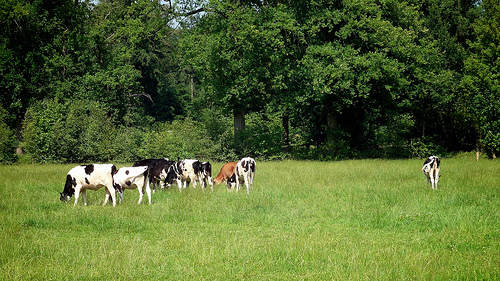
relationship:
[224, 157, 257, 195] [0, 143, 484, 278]
black and white cow in field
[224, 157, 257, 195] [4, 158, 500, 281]
black and white cow in field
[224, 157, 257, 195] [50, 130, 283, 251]
black and white cow in green grass field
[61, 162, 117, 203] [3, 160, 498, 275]
cow eating grass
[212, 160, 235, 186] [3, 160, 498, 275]
cow eating grass